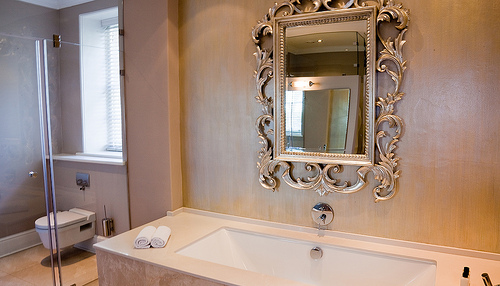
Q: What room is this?
A: It is a bathroom.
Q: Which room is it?
A: It is a bathroom.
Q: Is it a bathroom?
A: Yes, it is a bathroom.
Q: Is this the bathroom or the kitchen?
A: It is the bathroom.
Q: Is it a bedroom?
A: No, it is a bathroom.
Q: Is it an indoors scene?
A: Yes, it is indoors.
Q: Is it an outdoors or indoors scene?
A: It is indoors.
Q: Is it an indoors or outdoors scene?
A: It is indoors.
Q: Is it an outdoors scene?
A: No, it is indoors.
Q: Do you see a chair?
A: No, there are no chairs.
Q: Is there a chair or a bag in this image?
A: No, there are no chairs or bags.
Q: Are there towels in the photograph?
A: Yes, there is a towel.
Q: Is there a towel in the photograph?
A: Yes, there is a towel.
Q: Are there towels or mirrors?
A: Yes, there is a towel.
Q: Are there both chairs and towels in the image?
A: No, there is a towel but no chairs.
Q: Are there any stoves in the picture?
A: No, there are no stoves.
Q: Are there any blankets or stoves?
A: No, there are no stoves or blankets.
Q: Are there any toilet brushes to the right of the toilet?
A: No, there is a towel to the right of the toilet.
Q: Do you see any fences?
A: No, there are no fences.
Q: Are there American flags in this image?
A: No, there are no American flags.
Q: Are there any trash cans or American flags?
A: No, there are no American flags or trash cans.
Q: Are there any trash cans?
A: No, there are no trash cans.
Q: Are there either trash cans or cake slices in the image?
A: No, there are no trash cans or cake slices.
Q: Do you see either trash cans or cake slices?
A: No, there are no trash cans or cake slices.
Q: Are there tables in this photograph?
A: No, there are no tables.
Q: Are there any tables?
A: No, there are no tables.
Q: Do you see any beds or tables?
A: No, there are no tables or beds.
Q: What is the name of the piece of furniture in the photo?
A: The piece of furniture is a shelf.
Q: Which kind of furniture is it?
A: The piece of furniture is a shelf.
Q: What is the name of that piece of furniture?
A: This is a shelf.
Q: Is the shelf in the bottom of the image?
A: Yes, the shelf is in the bottom of the image.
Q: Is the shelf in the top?
A: No, the shelf is in the bottom of the image.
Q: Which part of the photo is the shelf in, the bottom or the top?
A: The shelf is in the bottom of the image.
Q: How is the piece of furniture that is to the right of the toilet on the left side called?
A: The piece of furniture is a shelf.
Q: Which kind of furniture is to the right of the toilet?
A: The piece of furniture is a shelf.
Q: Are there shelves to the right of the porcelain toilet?
A: Yes, there is a shelf to the right of the toilet.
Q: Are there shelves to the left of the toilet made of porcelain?
A: No, the shelf is to the right of the toilet.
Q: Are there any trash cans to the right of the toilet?
A: No, there is a shelf to the right of the toilet.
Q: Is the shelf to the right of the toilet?
A: Yes, the shelf is to the right of the toilet.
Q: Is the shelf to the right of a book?
A: No, the shelf is to the right of the toilet.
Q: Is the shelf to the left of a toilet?
A: No, the shelf is to the right of a toilet.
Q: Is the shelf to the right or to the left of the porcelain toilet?
A: The shelf is to the right of the toilet.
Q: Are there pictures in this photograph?
A: No, there are no pictures.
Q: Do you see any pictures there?
A: No, there are no pictures.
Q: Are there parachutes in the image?
A: No, there are no parachutes.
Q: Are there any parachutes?
A: No, there are no parachutes.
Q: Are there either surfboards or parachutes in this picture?
A: No, there are no parachutes or surfboards.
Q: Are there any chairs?
A: No, there are no chairs.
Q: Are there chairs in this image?
A: No, there are no chairs.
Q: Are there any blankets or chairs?
A: No, there are no chairs or blankets.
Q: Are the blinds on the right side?
A: No, the blinds are on the left of the image.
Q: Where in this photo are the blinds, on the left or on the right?
A: The blinds are on the left of the image.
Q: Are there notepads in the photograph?
A: No, there are no notepads.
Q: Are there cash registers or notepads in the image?
A: No, there are no notepads or cash registers.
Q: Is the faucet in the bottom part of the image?
A: Yes, the faucet is in the bottom of the image.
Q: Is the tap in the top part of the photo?
A: No, the tap is in the bottom of the image.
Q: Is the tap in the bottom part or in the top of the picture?
A: The tap is in the bottom of the image.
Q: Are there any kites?
A: No, there are no kites.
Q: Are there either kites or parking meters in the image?
A: No, there are no kites or parking meters.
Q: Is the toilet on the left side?
A: Yes, the toilet is on the left of the image.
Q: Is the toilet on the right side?
A: No, the toilet is on the left of the image.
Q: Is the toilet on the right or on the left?
A: The toilet is on the left of the image.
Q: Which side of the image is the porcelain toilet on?
A: The toilet is on the left of the image.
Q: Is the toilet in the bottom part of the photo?
A: Yes, the toilet is in the bottom of the image.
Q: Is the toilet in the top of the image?
A: No, the toilet is in the bottom of the image.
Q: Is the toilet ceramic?
A: Yes, the toilet is ceramic.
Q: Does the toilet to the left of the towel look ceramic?
A: Yes, the toilet is ceramic.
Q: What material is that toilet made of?
A: The toilet is made of porcelain.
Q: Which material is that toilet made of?
A: The toilet is made of porcelain.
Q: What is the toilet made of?
A: The toilet is made of porcelain.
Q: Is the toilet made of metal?
A: No, the toilet is made of porcelain.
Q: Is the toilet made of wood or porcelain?
A: The toilet is made of porcelain.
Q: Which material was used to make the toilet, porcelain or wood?
A: The toilet is made of porcelain.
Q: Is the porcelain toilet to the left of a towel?
A: Yes, the toilet is to the left of a towel.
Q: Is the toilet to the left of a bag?
A: No, the toilet is to the left of a towel.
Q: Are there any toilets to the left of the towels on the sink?
A: Yes, there is a toilet to the left of the towels.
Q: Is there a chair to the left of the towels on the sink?
A: No, there is a toilet to the left of the towels.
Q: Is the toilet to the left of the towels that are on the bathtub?
A: Yes, the toilet is to the left of the towels.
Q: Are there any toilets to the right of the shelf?
A: No, the toilet is to the left of the shelf.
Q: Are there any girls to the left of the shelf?
A: No, there is a toilet to the left of the shelf.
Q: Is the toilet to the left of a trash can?
A: No, the toilet is to the left of the shelf.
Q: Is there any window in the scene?
A: Yes, there is a window.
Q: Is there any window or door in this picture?
A: Yes, there is a window.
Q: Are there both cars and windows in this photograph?
A: No, there is a window but no cars.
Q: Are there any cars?
A: No, there are no cars.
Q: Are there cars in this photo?
A: No, there are no cars.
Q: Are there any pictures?
A: No, there are no pictures.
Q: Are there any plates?
A: No, there are no plates.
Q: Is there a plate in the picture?
A: No, there are no plates.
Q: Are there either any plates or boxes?
A: No, there are no plates or boxes.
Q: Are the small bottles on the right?
A: Yes, the bottles are on the right of the image.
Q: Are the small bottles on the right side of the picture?
A: Yes, the bottles are on the right of the image.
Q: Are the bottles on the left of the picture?
A: No, the bottles are on the right of the image.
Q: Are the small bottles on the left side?
A: No, the bottles are on the right of the image.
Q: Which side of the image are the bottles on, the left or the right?
A: The bottles are on the right of the image.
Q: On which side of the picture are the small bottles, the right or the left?
A: The bottles are on the right of the image.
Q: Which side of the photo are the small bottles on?
A: The bottles are on the right of the image.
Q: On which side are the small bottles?
A: The bottles are on the right of the image.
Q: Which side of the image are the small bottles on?
A: The bottles are on the right of the image.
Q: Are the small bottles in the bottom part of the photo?
A: Yes, the bottles are in the bottom of the image.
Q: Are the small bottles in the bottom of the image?
A: Yes, the bottles are in the bottom of the image.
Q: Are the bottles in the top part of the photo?
A: No, the bottles are in the bottom of the image.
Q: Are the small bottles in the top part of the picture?
A: No, the bottles are in the bottom of the image.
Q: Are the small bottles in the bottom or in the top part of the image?
A: The bottles are in the bottom of the image.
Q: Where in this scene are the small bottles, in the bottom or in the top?
A: The bottles are in the bottom of the image.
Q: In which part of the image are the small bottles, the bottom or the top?
A: The bottles are in the bottom of the image.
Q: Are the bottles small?
A: Yes, the bottles are small.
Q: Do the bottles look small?
A: Yes, the bottles are small.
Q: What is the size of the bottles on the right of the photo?
A: The bottles are small.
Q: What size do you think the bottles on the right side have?
A: The bottles have small size.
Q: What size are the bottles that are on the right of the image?
A: The bottles are small.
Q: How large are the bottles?
A: The bottles are small.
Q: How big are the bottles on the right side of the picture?
A: The bottles are small.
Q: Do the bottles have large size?
A: No, the bottles are small.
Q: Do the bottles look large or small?
A: The bottles are small.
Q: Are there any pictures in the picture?
A: No, there are no pictures.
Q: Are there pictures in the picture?
A: No, there are no pictures.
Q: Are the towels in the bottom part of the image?
A: Yes, the towels are in the bottom of the image.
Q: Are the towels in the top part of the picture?
A: No, the towels are in the bottom of the image.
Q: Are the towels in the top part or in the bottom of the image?
A: The towels are in the bottom of the image.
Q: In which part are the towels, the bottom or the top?
A: The towels are in the bottom of the image.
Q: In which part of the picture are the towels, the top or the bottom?
A: The towels are in the bottom of the image.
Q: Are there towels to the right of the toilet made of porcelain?
A: Yes, there are towels to the right of the toilet.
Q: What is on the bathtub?
A: The towels are on the bathtub.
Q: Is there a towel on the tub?
A: Yes, there are towels on the tub.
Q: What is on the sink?
A: The towels are on the sink.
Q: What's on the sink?
A: The towels are on the sink.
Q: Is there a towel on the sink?
A: Yes, there are towels on the sink.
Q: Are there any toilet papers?
A: No, there are no toilet papers.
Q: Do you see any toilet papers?
A: No, there are no toilet papers.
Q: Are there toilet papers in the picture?
A: No, there are no toilet papers.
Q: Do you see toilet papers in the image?
A: No, there are no toilet papers.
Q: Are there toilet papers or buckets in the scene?
A: No, there are no toilet papers or buckets.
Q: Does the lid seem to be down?
A: Yes, the lid is down.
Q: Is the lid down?
A: Yes, the lid is down.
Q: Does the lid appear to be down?
A: Yes, the lid is down.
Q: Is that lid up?
A: No, the lid is down.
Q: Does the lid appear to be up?
A: No, the lid is down.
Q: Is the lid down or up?
A: The lid is down.